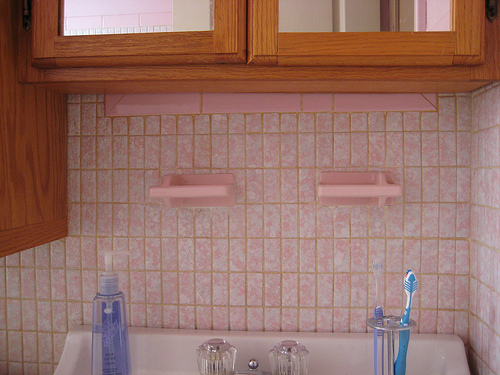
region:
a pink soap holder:
[320, 169, 402, 205]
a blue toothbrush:
[396, 265, 415, 368]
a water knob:
[268, 339, 309, 373]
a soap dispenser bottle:
[94, 244, 140, 373]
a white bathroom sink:
[49, 325, 476, 372]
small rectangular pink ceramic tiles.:
[178, 238, 368, 275]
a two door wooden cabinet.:
[29, 0, 495, 95]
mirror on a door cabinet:
[277, 0, 452, 32]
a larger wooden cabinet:
[0, 0, 70, 261]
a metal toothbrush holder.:
[369, 314, 410, 374]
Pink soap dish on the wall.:
[146, 160, 240, 212]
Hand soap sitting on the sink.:
[86, 245, 131, 373]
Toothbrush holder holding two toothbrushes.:
[366, 252, 419, 372]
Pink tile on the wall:
[205, 215, 332, 316]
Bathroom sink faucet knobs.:
[190, 335, 316, 373]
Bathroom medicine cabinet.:
[0, 24, 497, 91]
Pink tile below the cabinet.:
[98, 93, 441, 114]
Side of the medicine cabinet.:
[0, 87, 70, 256]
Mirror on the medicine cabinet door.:
[35, 1, 239, 63]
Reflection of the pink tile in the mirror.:
[63, 0, 173, 32]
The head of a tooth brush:
[401, 268, 417, 297]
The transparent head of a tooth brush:
[373, 257, 381, 278]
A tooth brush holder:
[369, 322, 416, 339]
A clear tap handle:
[195, 339, 235, 371]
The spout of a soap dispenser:
[105, 247, 131, 256]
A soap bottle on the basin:
[93, 297, 126, 374]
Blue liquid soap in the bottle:
[105, 311, 121, 366]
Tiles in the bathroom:
[148, 250, 268, 299]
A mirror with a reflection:
[69, 6, 201, 28]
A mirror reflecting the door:
[296, 6, 373, 28]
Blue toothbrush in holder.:
[393, 270, 415, 372]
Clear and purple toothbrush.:
[371, 258, 386, 374]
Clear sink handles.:
[195, 339, 314, 374]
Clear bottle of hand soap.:
[92, 247, 132, 372]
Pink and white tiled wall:
[214, 235, 328, 292]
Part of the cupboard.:
[23, 30, 81, 80]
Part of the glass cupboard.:
[74, 11, 183, 35]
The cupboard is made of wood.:
[21, 105, 61, 194]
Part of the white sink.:
[146, 335, 179, 374]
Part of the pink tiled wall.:
[96, 98, 160, 123]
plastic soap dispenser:
[86, 245, 136, 373]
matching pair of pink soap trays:
[141, 166, 407, 210]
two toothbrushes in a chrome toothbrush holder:
[361, 252, 421, 374]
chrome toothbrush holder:
[363, 310, 417, 373]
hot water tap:
[193, 333, 237, 373]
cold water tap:
[263, 337, 310, 374]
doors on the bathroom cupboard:
[21, 0, 497, 71]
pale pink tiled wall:
[0, 73, 498, 373]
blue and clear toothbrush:
[369, 244, 386, 371]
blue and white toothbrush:
[391, 265, 420, 373]